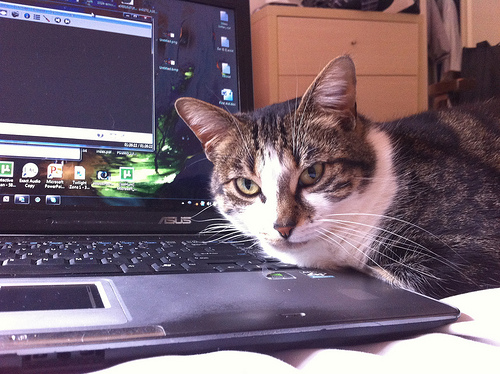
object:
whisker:
[322, 210, 483, 275]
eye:
[299, 159, 326, 188]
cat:
[175, 53, 495, 296]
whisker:
[192, 201, 215, 217]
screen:
[0, 4, 236, 215]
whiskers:
[211, 84, 317, 163]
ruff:
[260, 128, 400, 273]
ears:
[169, 58, 359, 155]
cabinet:
[244, 5, 427, 127]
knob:
[347, 37, 362, 48]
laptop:
[0, 0, 461, 372]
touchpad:
[0, 276, 102, 318]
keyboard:
[0, 230, 291, 281]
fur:
[367, 93, 500, 296]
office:
[250, 3, 498, 148]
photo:
[1, 1, 500, 372]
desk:
[3, 281, 500, 371]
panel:
[2, 263, 453, 341]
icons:
[215, 9, 237, 113]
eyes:
[230, 171, 265, 205]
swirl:
[80, 82, 194, 199]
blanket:
[1, 282, 498, 373]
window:
[1, 1, 165, 150]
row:
[211, 7, 245, 113]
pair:
[163, 57, 173, 60]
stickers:
[170, 63, 173, 64]